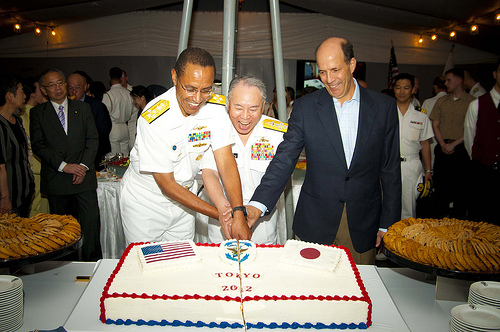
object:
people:
[29, 68, 103, 262]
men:
[115, 47, 253, 244]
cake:
[99, 239, 373, 330]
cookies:
[429, 246, 447, 268]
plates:
[0, 275, 23, 292]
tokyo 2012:
[214, 273, 260, 292]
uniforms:
[116, 85, 238, 245]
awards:
[246, 139, 275, 163]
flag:
[140, 242, 197, 262]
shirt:
[428, 91, 475, 141]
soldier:
[429, 68, 477, 220]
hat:
[414, 174, 432, 199]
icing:
[102, 297, 244, 324]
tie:
[56, 104, 69, 127]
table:
[0, 261, 500, 331]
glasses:
[37, 79, 65, 90]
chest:
[177, 128, 212, 155]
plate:
[470, 280, 500, 301]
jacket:
[248, 84, 404, 253]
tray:
[378, 237, 500, 283]